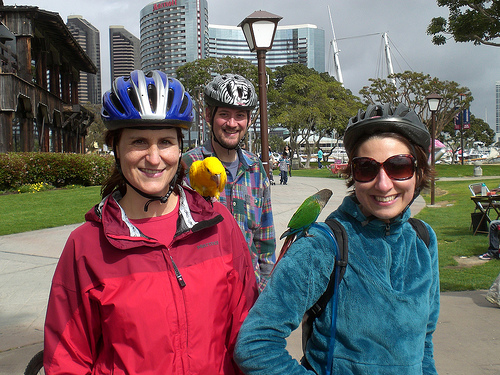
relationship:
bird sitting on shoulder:
[183, 149, 235, 201] [186, 192, 234, 226]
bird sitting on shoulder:
[264, 185, 335, 272] [302, 212, 351, 263]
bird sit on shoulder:
[183, 149, 235, 201] [186, 192, 234, 226]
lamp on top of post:
[236, 7, 281, 50] [257, 53, 276, 168]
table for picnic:
[330, 160, 348, 174] [327, 162, 346, 172]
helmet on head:
[337, 95, 434, 158] [334, 130, 438, 241]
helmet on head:
[91, 60, 202, 136] [102, 124, 195, 208]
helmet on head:
[201, 68, 264, 128] [203, 104, 256, 156]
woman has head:
[225, 91, 453, 374] [334, 130, 438, 241]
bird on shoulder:
[183, 149, 235, 201] [186, 192, 234, 226]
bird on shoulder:
[264, 185, 335, 272] [302, 212, 351, 263]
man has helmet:
[187, 64, 287, 259] [201, 68, 264, 128]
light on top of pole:
[236, 7, 281, 50] [257, 53, 276, 168]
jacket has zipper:
[37, 184, 265, 374] [164, 245, 201, 374]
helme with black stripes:
[201, 68, 264, 128] [202, 67, 263, 112]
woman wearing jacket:
[225, 91, 453, 374] [228, 205, 454, 374]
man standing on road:
[176, 71, 279, 294] [5, 231, 46, 360]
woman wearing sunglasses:
[225, 91, 453, 374] [348, 151, 421, 183]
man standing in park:
[187, 64, 287, 259] [440, 185, 500, 371]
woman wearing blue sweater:
[225, 91, 453, 374] [228, 205, 454, 374]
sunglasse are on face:
[348, 151, 421, 183] [334, 130, 438, 241]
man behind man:
[187, 64, 287, 259] [176, 71, 279, 294]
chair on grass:
[467, 175, 497, 233] [434, 152, 499, 288]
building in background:
[127, 1, 332, 86] [4, 5, 500, 65]